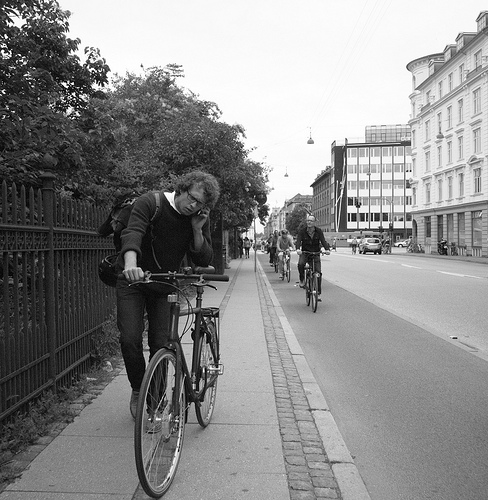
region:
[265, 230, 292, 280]
row of bikers in distance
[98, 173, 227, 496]
man walking his bike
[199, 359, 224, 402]
foot pedal of bike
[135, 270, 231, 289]
bike has straight handle bars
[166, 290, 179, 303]
reflector on front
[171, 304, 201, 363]
a dark color bike frame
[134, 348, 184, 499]
thin wheels of adult bike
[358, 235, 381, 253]
rear facing car in distance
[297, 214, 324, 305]
bike rider in the lead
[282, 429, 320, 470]
rows of bricks on sidewalk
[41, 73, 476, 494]
the picture is black and white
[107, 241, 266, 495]
the bike is dark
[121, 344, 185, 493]
the wheel is black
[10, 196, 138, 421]
the gate is to the left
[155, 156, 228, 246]
the man is holding a phone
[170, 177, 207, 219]
the man is wearing glasses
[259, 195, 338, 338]
the people are riding bikes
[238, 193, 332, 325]
the people are in motion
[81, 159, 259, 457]
the man is walking with his bike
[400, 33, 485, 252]
the building is light colored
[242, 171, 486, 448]
A city street.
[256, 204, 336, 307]
People ride bicycles on the street.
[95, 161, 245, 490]
A man on the sidewalk.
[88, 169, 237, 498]
The man on the sidewalk is talking on a phone.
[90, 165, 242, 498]
The man on the cellphone is holding a bicycle.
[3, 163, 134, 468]
A metal fence beside the sidewalk.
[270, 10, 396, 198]
Wires with objects hanging from them.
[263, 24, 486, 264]
Buildings along the side of the road.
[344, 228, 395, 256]
A car parked at the sidewalk.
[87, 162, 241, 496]
The man with the bicycle is wearing a back pack.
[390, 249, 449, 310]
street for vehicles to travel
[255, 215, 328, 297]
bike riders in a line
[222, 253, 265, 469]
sidewalk for the pedestrians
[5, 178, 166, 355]
fence along the sidewalk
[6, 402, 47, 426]
plants at bottom of fence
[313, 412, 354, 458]
curb on the sidewalk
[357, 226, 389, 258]
vehicle on the street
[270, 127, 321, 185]
lights hanging over street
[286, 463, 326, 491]
brick area of sidewalk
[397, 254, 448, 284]
line dividing street lanes